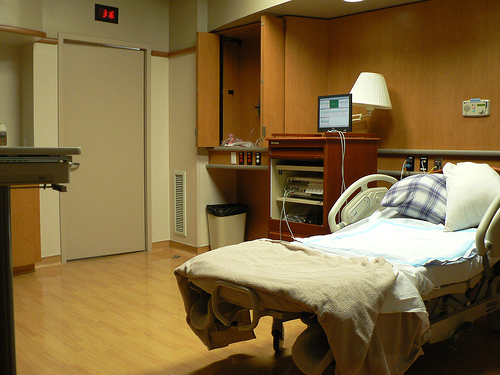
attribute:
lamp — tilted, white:
[354, 70, 389, 118]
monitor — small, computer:
[315, 97, 350, 131]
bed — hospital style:
[187, 124, 497, 351]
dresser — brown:
[267, 131, 381, 242]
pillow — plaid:
[383, 164, 440, 229]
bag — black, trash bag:
[184, 184, 244, 226]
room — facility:
[0, 2, 497, 374]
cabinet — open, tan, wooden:
[196, 14, 282, 147]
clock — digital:
[92, 2, 121, 25]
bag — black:
[204, 200, 249, 217]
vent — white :
[174, 170, 185, 237]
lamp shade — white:
[352, 70, 394, 112]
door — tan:
[60, 40, 145, 262]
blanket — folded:
[171, 236, 433, 373]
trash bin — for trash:
[199, 204, 255, 251]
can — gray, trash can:
[202, 195, 249, 255]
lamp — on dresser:
[348, 70, 393, 121]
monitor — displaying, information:
[309, 88, 354, 135]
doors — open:
[193, 14, 283, 156]